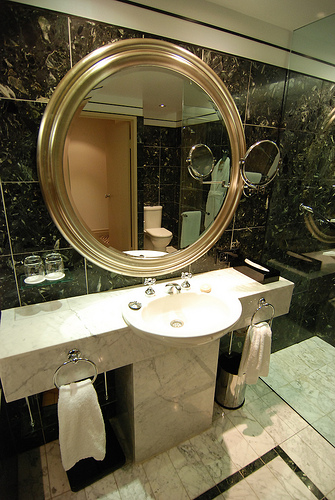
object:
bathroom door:
[105, 123, 131, 252]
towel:
[237, 322, 271, 387]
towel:
[57, 379, 106, 471]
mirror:
[241, 139, 280, 191]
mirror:
[33, 35, 246, 278]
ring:
[53, 355, 98, 391]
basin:
[122, 287, 243, 349]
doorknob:
[103, 192, 110, 202]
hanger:
[251, 297, 275, 328]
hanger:
[52, 348, 99, 390]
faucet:
[165, 282, 183, 294]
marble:
[0, 0, 71, 100]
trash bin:
[216, 350, 247, 410]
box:
[233, 255, 281, 285]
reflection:
[61, 70, 232, 260]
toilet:
[143, 204, 173, 251]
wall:
[0, 0, 290, 311]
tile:
[320, 486, 335, 500]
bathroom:
[0, 0, 335, 500]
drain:
[168, 319, 182, 327]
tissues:
[244, 257, 270, 273]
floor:
[16, 333, 334, 500]